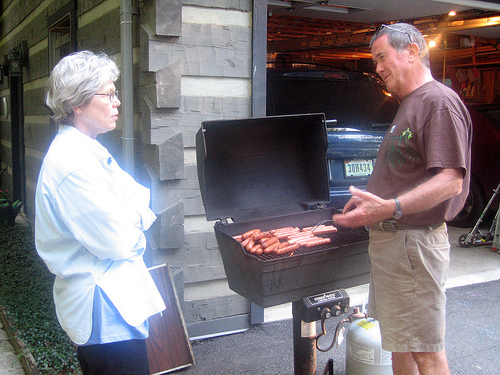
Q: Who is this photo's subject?
A: The couple.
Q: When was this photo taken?
A: During the day.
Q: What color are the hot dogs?
A: Red.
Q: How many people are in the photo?
A: 2.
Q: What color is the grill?
A: Black.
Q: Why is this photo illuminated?
A: Sunlight.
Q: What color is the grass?
A: Green.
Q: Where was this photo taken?
A: Outside a home near the garage.